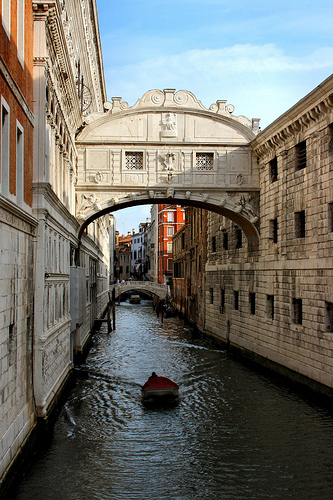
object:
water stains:
[204, 258, 332, 368]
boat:
[140, 372, 180, 405]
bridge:
[109, 281, 171, 302]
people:
[121, 279, 125, 283]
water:
[0, 302, 333, 500]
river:
[0, 302, 333, 500]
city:
[0, 0, 333, 500]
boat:
[129, 295, 141, 303]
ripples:
[82, 414, 271, 497]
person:
[117, 278, 120, 283]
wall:
[204, 116, 333, 384]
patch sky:
[96, 1, 333, 130]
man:
[148, 372, 158, 380]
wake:
[75, 359, 225, 393]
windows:
[124, 152, 214, 170]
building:
[0, 0, 333, 500]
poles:
[112, 287, 115, 329]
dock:
[94, 288, 115, 332]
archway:
[75, 88, 261, 249]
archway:
[109, 281, 172, 303]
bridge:
[76, 88, 261, 242]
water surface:
[0, 301, 332, 500]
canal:
[0, 294, 333, 500]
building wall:
[205, 73, 333, 387]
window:
[266, 294, 275, 320]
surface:
[176, 339, 317, 478]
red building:
[158, 203, 186, 283]